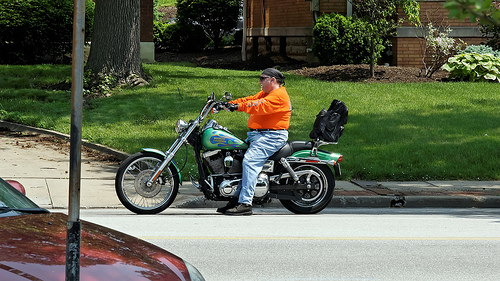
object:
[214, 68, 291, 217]
man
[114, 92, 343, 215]
motorcycle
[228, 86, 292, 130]
jacket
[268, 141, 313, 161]
seat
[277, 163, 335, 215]
tire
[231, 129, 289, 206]
pants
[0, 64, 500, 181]
grass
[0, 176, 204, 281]
car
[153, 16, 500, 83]
landscaping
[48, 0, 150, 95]
trunk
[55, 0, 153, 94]
tree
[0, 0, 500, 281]
sunlight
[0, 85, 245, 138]
shadow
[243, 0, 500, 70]
building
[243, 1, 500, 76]
exterior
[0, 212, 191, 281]
hood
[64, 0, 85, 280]
pole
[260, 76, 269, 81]
sunglasses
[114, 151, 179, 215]
wheel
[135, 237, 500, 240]
line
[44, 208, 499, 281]
road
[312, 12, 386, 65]
bush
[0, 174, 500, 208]
sidewalk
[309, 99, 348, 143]
bag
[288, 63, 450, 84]
dirt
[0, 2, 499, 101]
background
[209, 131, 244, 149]
flames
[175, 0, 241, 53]
bushes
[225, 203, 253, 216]
boots